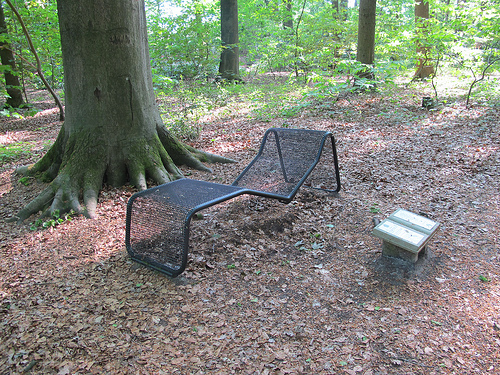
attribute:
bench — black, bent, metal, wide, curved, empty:
[125, 126, 343, 277]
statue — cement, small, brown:
[376, 201, 442, 272]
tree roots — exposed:
[15, 130, 234, 216]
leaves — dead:
[47, 236, 117, 298]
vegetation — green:
[269, 59, 365, 112]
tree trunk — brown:
[56, 5, 173, 137]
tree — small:
[290, 9, 358, 88]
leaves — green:
[314, 18, 334, 34]